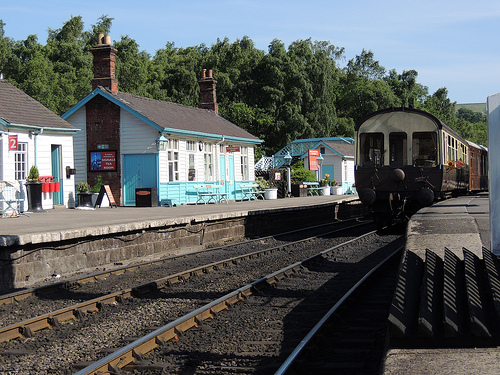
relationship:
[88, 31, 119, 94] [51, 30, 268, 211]
chimney on top of a building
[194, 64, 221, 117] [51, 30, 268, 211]
chimneys on top of a building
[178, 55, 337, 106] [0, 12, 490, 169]
leaves on trees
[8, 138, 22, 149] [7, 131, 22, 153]
number2 on sign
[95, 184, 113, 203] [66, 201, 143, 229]
sign on ground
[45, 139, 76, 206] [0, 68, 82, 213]
door on building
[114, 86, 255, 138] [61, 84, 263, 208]
roof on building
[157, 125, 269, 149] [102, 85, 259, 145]
edge on roof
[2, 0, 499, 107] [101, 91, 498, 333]
sky over station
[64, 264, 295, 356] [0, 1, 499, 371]
tracks at station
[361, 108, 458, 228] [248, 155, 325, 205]
train at station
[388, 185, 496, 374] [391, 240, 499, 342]
platform with ridges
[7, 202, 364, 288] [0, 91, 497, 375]
wall at station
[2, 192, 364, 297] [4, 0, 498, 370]
platform at train station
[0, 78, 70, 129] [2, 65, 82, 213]
roof of building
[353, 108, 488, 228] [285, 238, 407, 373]
train on tracks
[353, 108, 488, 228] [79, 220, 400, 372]
train on tracks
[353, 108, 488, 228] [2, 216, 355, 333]
train on tracks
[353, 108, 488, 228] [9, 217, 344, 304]
train on tracks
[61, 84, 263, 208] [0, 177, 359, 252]
building on platform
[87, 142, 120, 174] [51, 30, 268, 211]
sign on building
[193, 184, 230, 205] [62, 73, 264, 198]
chair near building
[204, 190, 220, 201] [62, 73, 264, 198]
chair near building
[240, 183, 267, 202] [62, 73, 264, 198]
chair near building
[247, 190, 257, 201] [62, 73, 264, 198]
chair near building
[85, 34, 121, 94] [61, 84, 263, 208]
chimney on building